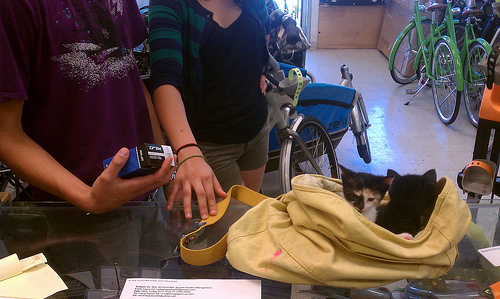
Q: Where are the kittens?
A: In the bag.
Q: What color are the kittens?
A: Black, brown, and white.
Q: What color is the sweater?
A: Green and blue.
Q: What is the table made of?
A: Glass.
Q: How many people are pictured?
A: Two.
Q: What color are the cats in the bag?
A: Black, white, and blonde.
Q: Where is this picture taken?
A: Bike store.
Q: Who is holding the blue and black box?
A: A man with a purple shirt.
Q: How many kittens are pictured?
A: Two.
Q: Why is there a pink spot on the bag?
A: Nailpolish stain.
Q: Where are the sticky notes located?
A: Glass display case.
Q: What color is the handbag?
A: Yellow.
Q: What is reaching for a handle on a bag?
A: A hand.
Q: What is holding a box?
A: A hand.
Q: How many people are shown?
A: Two.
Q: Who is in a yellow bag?
A: Two kittens.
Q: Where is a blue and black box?
A: On a hand.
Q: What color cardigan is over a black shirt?
A: Green and blue.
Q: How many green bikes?
A: Two.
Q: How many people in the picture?
A: Two.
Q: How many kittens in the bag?
A: Two.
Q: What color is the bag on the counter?
A: Tan.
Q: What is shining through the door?
A: Sunlight.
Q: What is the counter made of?
A: Glass.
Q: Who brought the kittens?
A: The people.